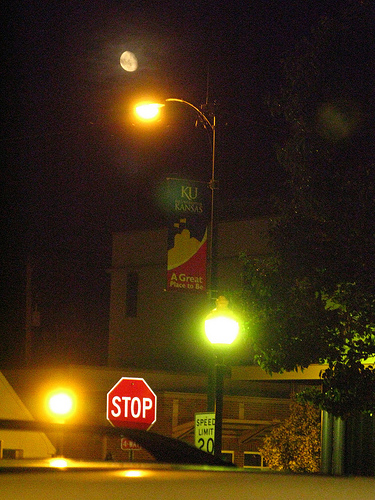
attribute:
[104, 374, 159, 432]
sign — red, white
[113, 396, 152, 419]
stop — white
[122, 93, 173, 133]
light — yellow, on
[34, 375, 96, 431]
light — yellow, on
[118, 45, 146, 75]
moon — bright, white, shining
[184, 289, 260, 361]
light — on, reflected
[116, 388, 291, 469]
wall — brick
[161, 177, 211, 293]
poster — hanging, verticle, red white, blue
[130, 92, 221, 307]
pole — tall, arched, lit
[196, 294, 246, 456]
lamp — bright, shining, glowing, lit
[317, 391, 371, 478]
planter — metal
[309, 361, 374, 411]
plant — green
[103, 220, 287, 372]
building — brick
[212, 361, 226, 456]
pole — black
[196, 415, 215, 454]
sign — black, white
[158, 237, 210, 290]
swirl — red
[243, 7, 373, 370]
tree — green, tall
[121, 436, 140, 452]
sign — small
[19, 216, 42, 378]
pole — wood